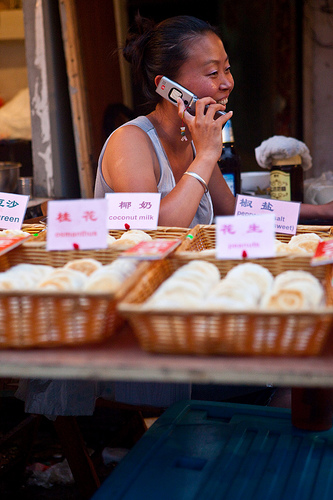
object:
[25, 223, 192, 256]
basket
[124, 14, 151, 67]
bun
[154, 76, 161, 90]
ear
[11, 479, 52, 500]
ground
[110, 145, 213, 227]
arm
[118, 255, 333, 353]
basket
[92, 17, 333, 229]
lady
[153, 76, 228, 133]
cell phone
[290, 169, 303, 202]
liquid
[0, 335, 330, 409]
table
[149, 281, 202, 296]
food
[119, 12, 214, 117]
hair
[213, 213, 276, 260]
food label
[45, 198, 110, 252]
food label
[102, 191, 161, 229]
food label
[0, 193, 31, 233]
food label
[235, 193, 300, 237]
food label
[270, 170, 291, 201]
label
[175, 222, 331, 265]
bascket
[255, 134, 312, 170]
leather couch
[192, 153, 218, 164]
wrist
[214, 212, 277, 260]
label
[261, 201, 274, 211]
letters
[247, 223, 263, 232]
letters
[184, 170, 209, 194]
bracelet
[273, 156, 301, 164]
top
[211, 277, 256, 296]
pastries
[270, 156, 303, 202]
jar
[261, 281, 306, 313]
desserts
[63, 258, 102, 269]
food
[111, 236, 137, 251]
food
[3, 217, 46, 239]
basket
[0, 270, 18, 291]
food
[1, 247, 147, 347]
basket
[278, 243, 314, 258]
food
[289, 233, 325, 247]
food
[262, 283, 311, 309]
food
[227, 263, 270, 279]
food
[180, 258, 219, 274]
food